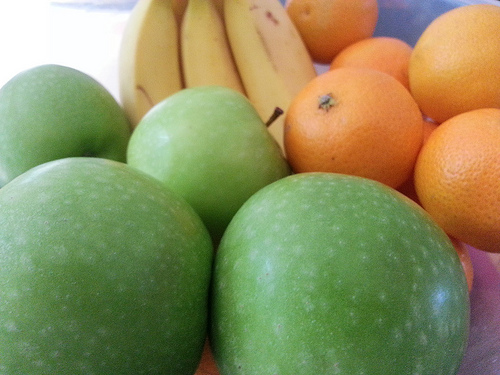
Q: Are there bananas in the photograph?
A: Yes, there is a banana.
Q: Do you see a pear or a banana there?
A: Yes, there is a banana.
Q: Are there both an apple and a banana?
A: Yes, there are both a banana and an apple.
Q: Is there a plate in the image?
A: No, there are no plates.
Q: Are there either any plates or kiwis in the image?
A: No, there are no plates or kiwis.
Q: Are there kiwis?
A: No, there are no kiwis.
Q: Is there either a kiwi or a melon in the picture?
A: No, there are no kiwis or melons.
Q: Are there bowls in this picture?
A: No, there are no bowls.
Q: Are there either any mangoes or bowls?
A: No, there are no bowls or mangoes.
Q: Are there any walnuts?
A: No, there are no walnuts.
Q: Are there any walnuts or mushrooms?
A: No, there are no walnuts or mushrooms.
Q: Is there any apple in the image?
A: Yes, there is an apple.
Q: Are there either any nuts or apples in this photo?
A: Yes, there is an apple.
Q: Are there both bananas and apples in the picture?
A: Yes, there are both an apple and a banana.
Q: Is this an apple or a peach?
A: This is an apple.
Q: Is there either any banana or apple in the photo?
A: Yes, there is an apple.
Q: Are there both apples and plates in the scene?
A: No, there is an apple but no plates.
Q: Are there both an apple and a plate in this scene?
A: No, there is an apple but no plates.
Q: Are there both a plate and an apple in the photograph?
A: No, there is an apple but no plates.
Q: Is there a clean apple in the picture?
A: Yes, there is a clean apple.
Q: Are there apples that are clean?
A: Yes, there is an apple that is clean.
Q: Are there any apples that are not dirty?
A: Yes, there is a clean apple.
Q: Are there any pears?
A: No, there are no pears.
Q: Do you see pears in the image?
A: No, there are no pears.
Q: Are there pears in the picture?
A: No, there are no pears.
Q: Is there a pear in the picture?
A: No, there are no pears.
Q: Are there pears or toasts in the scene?
A: No, there are no pears or toasts.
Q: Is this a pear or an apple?
A: This is an apple.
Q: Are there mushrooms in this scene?
A: No, there are no mushrooms.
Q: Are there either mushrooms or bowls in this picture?
A: No, there are no mushrooms or bowls.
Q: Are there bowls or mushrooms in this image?
A: No, there are no mushrooms or bowls.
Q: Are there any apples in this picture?
A: Yes, there is an apple.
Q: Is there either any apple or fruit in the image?
A: Yes, there is an apple.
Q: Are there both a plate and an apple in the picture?
A: No, there is an apple but no plates.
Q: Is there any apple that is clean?
A: Yes, there is a clean apple.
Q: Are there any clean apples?
A: Yes, there is a clean apple.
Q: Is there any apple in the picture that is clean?
A: Yes, there is an apple that is clean.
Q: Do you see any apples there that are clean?
A: Yes, there is an apple that is clean.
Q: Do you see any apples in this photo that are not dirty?
A: Yes, there is a clean apple.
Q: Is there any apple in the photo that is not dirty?
A: Yes, there is a clean apple.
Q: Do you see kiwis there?
A: No, there are no kiwis.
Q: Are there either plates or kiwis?
A: No, there are no kiwis or plates.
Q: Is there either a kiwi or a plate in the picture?
A: No, there are no kiwis or plates.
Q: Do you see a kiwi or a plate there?
A: No, there are no kiwis or plates.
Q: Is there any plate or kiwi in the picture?
A: No, there are no kiwis or plates.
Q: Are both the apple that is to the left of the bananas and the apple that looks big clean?
A: Yes, both the apple and the apple are clean.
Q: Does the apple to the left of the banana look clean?
A: Yes, the apple is clean.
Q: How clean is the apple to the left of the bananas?
A: The apple is clean.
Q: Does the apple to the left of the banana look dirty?
A: No, the apple is clean.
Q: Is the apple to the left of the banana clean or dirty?
A: The apple is clean.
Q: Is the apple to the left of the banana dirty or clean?
A: The apple is clean.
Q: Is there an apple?
A: Yes, there is an apple.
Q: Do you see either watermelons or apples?
A: Yes, there is an apple.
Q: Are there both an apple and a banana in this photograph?
A: Yes, there are both an apple and a banana.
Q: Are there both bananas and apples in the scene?
A: Yes, there are both an apple and a banana.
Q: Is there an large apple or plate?
A: Yes, there is a large apple.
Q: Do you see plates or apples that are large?
A: Yes, the apple is large.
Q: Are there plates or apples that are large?
A: Yes, the apple is large.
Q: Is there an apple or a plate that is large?
A: Yes, the apple is large.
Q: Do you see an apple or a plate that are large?
A: Yes, the apple is large.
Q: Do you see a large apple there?
A: Yes, there is a large apple.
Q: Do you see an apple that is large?
A: Yes, there is an apple that is large.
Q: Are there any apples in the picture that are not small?
A: Yes, there is a large apple.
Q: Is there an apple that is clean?
A: Yes, there is a clean apple.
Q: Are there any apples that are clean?
A: Yes, there is an apple that is clean.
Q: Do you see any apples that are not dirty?
A: Yes, there is a clean apple.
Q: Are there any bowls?
A: No, there are no bowls.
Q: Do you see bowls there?
A: No, there are no bowls.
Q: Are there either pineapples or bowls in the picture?
A: No, there are no bowls or pineapples.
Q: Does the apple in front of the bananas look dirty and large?
A: No, the apple is large but clean.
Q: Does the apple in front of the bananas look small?
A: No, the apple is large.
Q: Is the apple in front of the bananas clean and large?
A: Yes, the apple is clean and large.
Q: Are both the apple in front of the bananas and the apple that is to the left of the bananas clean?
A: Yes, both the apple and the apple are clean.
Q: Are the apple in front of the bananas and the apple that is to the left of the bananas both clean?
A: Yes, both the apple and the apple are clean.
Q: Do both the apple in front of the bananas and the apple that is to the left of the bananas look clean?
A: Yes, both the apple and the apple are clean.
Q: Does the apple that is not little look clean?
A: Yes, the apple is clean.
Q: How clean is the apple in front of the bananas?
A: The apple is clean.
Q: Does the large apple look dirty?
A: No, the apple is clean.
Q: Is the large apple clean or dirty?
A: The apple is clean.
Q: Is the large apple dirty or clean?
A: The apple is clean.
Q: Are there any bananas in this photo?
A: Yes, there are bananas.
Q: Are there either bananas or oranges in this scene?
A: Yes, there are bananas.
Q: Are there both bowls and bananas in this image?
A: No, there are bananas but no bowls.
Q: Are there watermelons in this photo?
A: No, there are no watermelons.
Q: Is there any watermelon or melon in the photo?
A: No, there are no watermelons or melons.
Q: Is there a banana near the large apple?
A: Yes, there are bananas near the apple.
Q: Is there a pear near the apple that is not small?
A: No, there are bananas near the apple.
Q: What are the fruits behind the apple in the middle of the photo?
A: The fruits are bananas.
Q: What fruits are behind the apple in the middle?
A: The fruits are bananas.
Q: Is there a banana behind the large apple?
A: Yes, there are bananas behind the apple.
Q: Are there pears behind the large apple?
A: No, there are bananas behind the apple.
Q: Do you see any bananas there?
A: Yes, there is a banana.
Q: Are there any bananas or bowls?
A: Yes, there is a banana.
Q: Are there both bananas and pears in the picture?
A: No, there is a banana but no pears.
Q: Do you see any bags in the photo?
A: No, there are no bags.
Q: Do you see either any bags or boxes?
A: No, there are no bags or boxes.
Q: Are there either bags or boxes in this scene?
A: No, there are no bags or boxes.